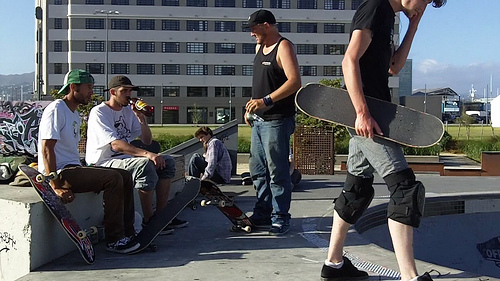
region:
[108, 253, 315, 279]
The ground is the color gray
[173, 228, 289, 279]
The ground is made of cement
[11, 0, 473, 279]
A group of men sitting around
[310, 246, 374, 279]
The foot of the man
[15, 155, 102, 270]
The skateboard sitting against the wall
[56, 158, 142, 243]
The man has on brown pants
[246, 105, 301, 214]
The man has on blue jeans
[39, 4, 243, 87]
The building has many windows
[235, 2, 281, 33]
The man has on a black hat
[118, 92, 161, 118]
The man is drinking a beverage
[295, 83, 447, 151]
a long black skateboard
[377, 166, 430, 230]
a man's black kneepad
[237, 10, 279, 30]
a black baseball cap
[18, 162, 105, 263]
a colorful skateboard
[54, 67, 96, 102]
a green and white baseball cap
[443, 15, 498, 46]
part of a blue sky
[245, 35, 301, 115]
a man's black tank top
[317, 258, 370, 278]
the shoe of a man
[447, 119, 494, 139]
a section of green grass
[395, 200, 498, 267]
a skateboard ramp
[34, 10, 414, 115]
tall building in background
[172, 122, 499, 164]
trimmed grass in background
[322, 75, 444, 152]
skateboard in man's hand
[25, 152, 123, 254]
skateboard leaning on wall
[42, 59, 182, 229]
two boys in white on wall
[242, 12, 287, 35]
black cap on man's head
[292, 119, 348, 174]
small waste bin behind boys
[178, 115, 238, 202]
boy sitting on stairs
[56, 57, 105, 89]
green hat on boy's head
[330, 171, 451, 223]
knee pads on boy's knees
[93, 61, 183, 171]
the man is drinking from a bottle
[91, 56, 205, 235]
the man is drinking from a bottle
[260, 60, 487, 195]
the skateboard is black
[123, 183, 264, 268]
the skateboard is black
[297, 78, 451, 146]
A skateboard in the picture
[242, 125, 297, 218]
A blue jeans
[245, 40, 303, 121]
A black vest in the photo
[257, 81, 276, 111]
A wrist band in the photo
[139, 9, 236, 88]
A building in the photo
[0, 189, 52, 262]
A concrete wall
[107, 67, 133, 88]
A black hat in the photo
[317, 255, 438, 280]
black shoes in the photo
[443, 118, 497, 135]
Grass in the field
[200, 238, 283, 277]
A paved floor